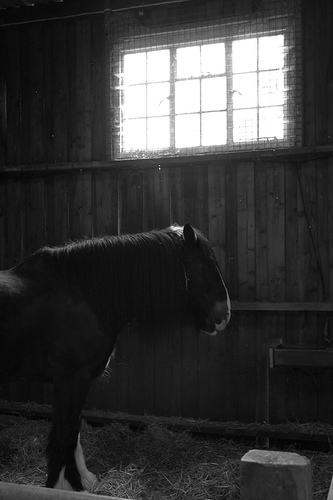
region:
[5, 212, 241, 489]
a horse stands over straw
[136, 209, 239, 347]
a white spot over head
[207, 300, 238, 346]
nose and mouth of horse are white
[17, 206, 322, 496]
a stone near a horse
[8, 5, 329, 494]
a window in a barn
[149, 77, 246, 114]
handles of a window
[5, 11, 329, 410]
wall of barn is made of wood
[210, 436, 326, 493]
a gray stone over straw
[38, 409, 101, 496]
lower part of legs are white and brown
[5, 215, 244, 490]
a brown and white horse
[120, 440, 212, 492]
The hay is on the ground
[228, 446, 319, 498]
The stool is made of cement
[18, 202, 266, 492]
A horse is standing on the barn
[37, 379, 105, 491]
The leg of the horse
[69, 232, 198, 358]
The mane of the horse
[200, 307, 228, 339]
The mouth of the horse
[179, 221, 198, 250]
The ear of the horse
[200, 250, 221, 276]
The eye of the horse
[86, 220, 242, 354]
The front of the horse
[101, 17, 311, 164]
The window has no curtains on it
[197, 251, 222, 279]
eye of the animal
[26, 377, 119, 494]
front legs of the animal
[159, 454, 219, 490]
hay under the horse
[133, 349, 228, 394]
wall next to the horse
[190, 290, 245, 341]
nose of the horse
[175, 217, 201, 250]
ear of the horse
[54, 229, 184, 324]
mane on the horse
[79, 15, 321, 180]
windows above the horse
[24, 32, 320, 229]
black and white photo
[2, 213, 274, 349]
side of the horse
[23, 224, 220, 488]
this is a horse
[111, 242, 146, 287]
this is the fur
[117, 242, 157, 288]
the fur is black in color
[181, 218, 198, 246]
this is the ear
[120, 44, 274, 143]
this is a window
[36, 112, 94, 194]
this is a wall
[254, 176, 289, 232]
the wall is wooden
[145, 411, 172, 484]
this is a grass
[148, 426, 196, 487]
the grass is dry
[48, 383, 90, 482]
this is the leg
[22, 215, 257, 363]
horse with a long mane and white nose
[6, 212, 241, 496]
a horse resting in its stall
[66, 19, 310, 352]
a horse standing under a window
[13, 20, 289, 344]
horse in a barn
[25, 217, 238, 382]
a dark horse with a white nose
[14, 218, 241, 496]
a dark horse with white feet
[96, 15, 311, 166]
a screened in window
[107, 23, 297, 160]
daylight coming through window in dark barn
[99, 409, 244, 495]
hay in a horse stall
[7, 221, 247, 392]
a horse looking at food